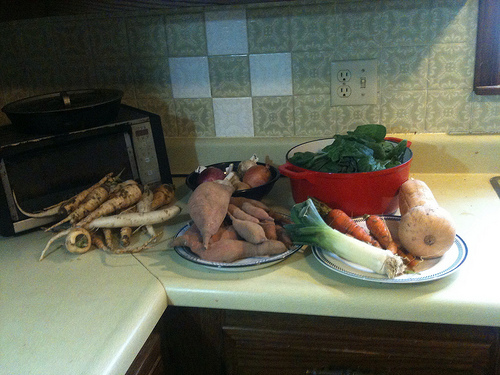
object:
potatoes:
[188, 180, 229, 251]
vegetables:
[149, 182, 176, 211]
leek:
[284, 198, 406, 278]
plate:
[173, 211, 306, 274]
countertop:
[105, 173, 500, 328]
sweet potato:
[228, 213, 265, 244]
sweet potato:
[241, 201, 275, 222]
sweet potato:
[260, 219, 277, 239]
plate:
[312, 215, 467, 285]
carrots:
[364, 214, 394, 249]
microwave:
[0, 104, 174, 237]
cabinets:
[153, 304, 499, 375]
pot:
[277, 137, 415, 222]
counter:
[0, 230, 167, 374]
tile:
[242, 52, 294, 100]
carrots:
[309, 196, 382, 249]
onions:
[243, 164, 273, 188]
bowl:
[184, 160, 283, 202]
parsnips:
[43, 181, 112, 231]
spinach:
[384, 140, 406, 158]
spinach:
[346, 124, 384, 143]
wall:
[0, 0, 500, 140]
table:
[114, 170, 500, 375]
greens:
[319, 133, 374, 163]